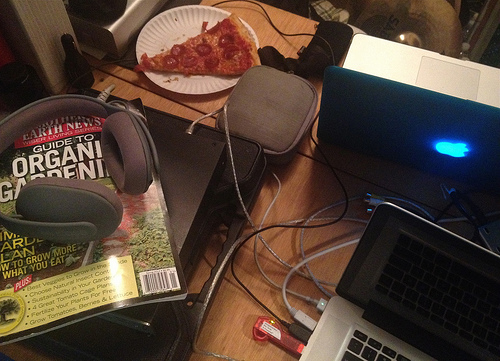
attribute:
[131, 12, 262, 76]
pizza — pepperoni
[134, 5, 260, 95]
plate — paper, white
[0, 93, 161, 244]
head phone — large, over the ear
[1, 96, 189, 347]
magazine — edition, organic gardening, guide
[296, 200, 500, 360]
laptop — off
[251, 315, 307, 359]
flash drive — red, removable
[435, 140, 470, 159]
logo — apple, lit, blue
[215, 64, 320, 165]
compact disc wallet — grey, portable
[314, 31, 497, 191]
laptop — apple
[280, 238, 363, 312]
cable — tangled, grey